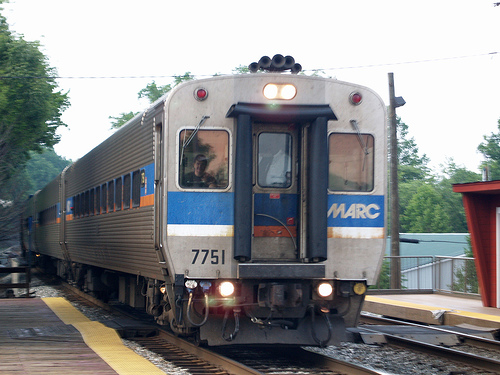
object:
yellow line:
[40, 296, 170, 375]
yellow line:
[363, 292, 500, 322]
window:
[326, 131, 376, 192]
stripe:
[38, 164, 154, 227]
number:
[201, 250, 209, 265]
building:
[452, 177, 498, 310]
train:
[23, 54, 390, 347]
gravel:
[300, 340, 488, 374]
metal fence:
[163, 73, 386, 346]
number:
[192, 249, 200, 265]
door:
[253, 116, 304, 265]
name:
[327, 203, 382, 219]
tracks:
[154, 324, 265, 374]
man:
[183, 154, 216, 188]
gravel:
[120, 309, 189, 374]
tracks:
[299, 346, 386, 374]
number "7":
[211, 249, 220, 264]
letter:
[325, 203, 344, 218]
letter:
[356, 203, 367, 219]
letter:
[365, 203, 381, 219]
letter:
[344, 204, 355, 219]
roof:
[387, 232, 469, 242]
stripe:
[129, 335, 237, 374]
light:
[262, 83, 279, 100]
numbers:
[222, 249, 226, 264]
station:
[0, 179, 500, 367]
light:
[218, 281, 235, 298]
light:
[318, 282, 334, 297]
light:
[280, 83, 298, 101]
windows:
[36, 169, 142, 225]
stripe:
[165, 192, 236, 237]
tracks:
[37, 261, 500, 374]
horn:
[249, 54, 302, 74]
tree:
[0, 1, 72, 215]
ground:
[32, 285, 117, 321]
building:
[397, 232, 468, 291]